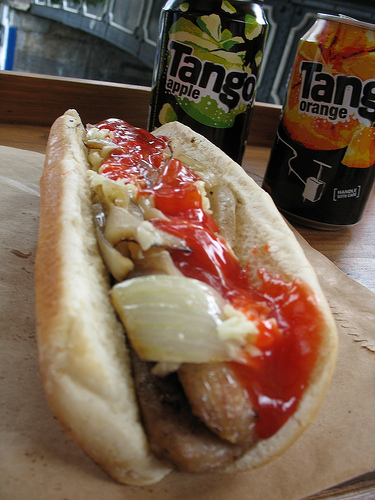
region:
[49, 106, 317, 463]
A hot dog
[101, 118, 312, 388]
Condiment on a hot dog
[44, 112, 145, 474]
Side of hot dog bun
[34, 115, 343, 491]
Hot dog on top of paper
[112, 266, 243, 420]
Onion on a hot dog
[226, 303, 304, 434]
Ketchup on a hot dog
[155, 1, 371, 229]
Cans of soda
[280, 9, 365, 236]
Orange can of soda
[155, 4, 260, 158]
Can of apple flavor soda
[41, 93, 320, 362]
onions on the bun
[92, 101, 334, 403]
ketchup on the bun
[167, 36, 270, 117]
Tango apple on the can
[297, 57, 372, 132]
Tango orange on the can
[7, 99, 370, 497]
hot dog on a napkin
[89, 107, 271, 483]
hot dog on a bun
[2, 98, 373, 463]
bun is open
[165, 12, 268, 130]
can has green and black colors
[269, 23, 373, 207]
can has orange and black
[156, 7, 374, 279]
cans next to the hot dog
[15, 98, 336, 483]
this is a hot dog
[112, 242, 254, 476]
a sausage on the hot dog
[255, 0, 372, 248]
this is a can of juice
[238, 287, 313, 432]
this is tomato sauce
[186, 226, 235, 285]
this is tomato sauce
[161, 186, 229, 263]
this is tomato sauce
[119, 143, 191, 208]
this is tomato sauce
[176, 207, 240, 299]
this is tomato sauce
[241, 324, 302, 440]
this is tomato sauce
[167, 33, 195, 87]
The letter is black.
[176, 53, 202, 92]
The letter is black.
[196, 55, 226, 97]
The letter is black.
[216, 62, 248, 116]
The letter is black.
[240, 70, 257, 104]
The letter is black.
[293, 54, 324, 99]
The letter is black.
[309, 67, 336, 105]
The letter is black.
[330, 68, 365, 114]
The letter is black.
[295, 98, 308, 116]
The letter is black.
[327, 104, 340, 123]
The letter is black.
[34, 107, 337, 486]
Hotdog with condiments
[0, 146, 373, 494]
Brown napkin under hotdog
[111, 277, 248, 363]
Large piece of onion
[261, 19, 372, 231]
Orange Tango soda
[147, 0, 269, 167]
Apple Tango soda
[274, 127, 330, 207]
Cartoon of TNT detonator and wire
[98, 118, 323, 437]
Ketchup on hot dog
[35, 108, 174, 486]
Left side of hot dog bun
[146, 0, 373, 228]
Two soda cans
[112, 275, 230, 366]
Slice of onion on the hot dog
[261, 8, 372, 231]
the orange tango can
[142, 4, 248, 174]
the green tango can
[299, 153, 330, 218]
the explosive detonator on the can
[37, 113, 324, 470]
the large sausage dog